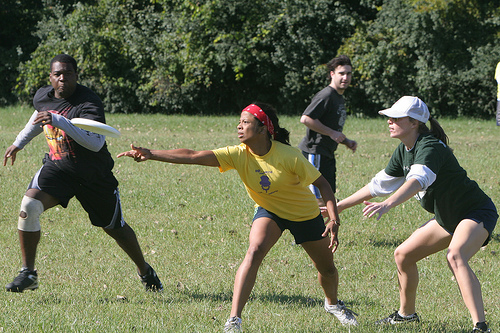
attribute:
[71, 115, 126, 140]
frisbee — ultimate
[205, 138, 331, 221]
tee shirt — yellow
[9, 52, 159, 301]
person — four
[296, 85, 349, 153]
shirt — black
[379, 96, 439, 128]
cap — white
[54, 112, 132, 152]
frisbee — white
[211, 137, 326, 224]
shirt — yellow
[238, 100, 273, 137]
bandana — red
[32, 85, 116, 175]
shirt — black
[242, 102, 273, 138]
headband — red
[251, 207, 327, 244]
pant — short